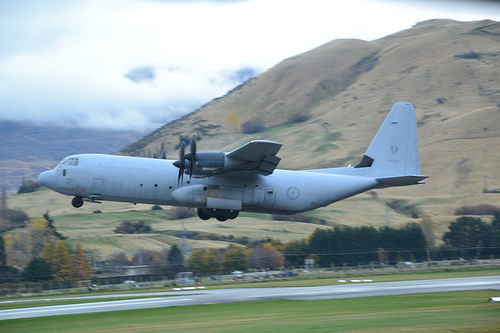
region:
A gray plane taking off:
[34, 99, 437, 262]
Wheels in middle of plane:
[190, 198, 239, 230]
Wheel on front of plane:
[74, 191, 84, 212]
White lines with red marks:
[168, 282, 213, 296]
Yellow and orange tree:
[48, 240, 100, 295]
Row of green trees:
[297, 210, 448, 284]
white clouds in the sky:
[73, 40, 254, 134]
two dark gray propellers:
[170, 132, 254, 202]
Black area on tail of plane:
[352, 151, 390, 176]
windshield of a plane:
[50, 153, 84, 171]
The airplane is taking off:
[36, 99, 429, 219]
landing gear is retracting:
[69, 196, 239, 221]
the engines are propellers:
[171, 138, 201, 186]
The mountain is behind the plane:
[1, 15, 498, 247]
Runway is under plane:
[1, 275, 499, 321]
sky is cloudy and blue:
[1, 2, 499, 127]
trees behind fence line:
[3, 201, 499, 298]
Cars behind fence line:
[0, 248, 498, 298]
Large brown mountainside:
[124, 20, 498, 241]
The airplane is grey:
[36, 98, 425, 223]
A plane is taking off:
[34, 95, 444, 240]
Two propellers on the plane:
[165, 138, 214, 195]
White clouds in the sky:
[14, 23, 385, 119]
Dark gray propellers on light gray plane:
[35, 100, 447, 215]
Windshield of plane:
[55, 151, 85, 174]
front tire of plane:
[64, 188, 94, 221]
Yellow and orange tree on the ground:
[42, 235, 108, 294]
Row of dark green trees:
[306, 226, 433, 275]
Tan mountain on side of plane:
[105, 22, 499, 295]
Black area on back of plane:
[349, 149, 382, 174]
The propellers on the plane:
[157, 125, 222, 192]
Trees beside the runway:
[305, 220, 497, 270]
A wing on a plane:
[141, 122, 302, 202]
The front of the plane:
[37, 152, 191, 205]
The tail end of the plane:
[344, 88, 431, 200]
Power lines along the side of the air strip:
[201, 235, 498, 290]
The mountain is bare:
[285, 27, 477, 182]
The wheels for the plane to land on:
[174, 195, 258, 229]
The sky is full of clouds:
[12, 11, 110, 91]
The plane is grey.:
[29, 132, 442, 226]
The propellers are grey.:
[163, 134, 222, 180]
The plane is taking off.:
[18, 112, 462, 244]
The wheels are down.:
[59, 190, 268, 250]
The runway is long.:
[100, 267, 495, 319]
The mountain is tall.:
[108, 3, 491, 262]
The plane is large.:
[32, 96, 422, 237]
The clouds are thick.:
[16, 9, 383, 141]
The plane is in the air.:
[29, 92, 464, 268]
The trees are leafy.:
[41, 219, 489, 293]